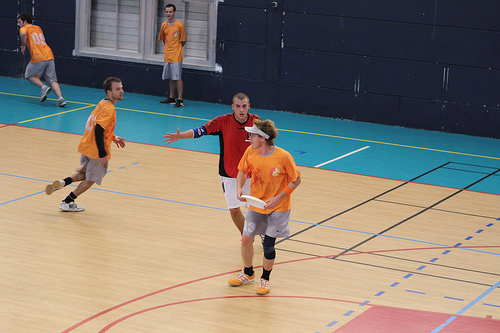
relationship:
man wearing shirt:
[42, 75, 128, 216] [78, 98, 115, 160]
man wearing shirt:
[227, 118, 301, 293] [237, 145, 297, 211]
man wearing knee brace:
[227, 118, 301, 293] [263, 235, 276, 258]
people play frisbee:
[202, 120, 330, 246] [241, 191, 271, 214]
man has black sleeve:
[42, 75, 128, 216] [93, 123, 108, 158]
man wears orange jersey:
[227, 118, 301, 297] [222, 147, 355, 207]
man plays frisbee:
[227, 118, 301, 297] [236, 192, 269, 214]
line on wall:
[343, 40, 437, 68] [316, 8, 478, 144]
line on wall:
[363, 2, 447, 42] [316, 8, 478, 144]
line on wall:
[346, 82, 430, 112] [316, 8, 478, 144]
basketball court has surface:
[2, 73, 497, 331] [7, 89, 497, 326]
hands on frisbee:
[233, 187, 276, 210] [236, 189, 273, 213]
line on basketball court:
[291, 213, 498, 314] [0, 72, 499, 332]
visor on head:
[239, 109, 271, 151] [246, 116, 280, 146]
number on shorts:
[242, 217, 257, 234] [244, 213, 295, 240]